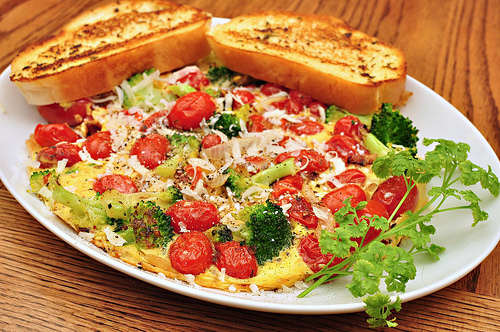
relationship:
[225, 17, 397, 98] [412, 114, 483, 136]
bread on plate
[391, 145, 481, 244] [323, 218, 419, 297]
sprig of parsley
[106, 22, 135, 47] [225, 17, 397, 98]
seasoning on bread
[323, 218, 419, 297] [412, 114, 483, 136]
parsley on plate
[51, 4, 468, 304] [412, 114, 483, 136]
food on plate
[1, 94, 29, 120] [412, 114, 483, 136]
part of plate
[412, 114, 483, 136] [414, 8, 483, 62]
plate on table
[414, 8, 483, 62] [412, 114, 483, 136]
table under plate